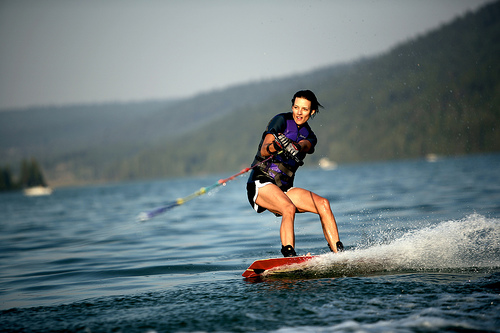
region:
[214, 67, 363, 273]
a woman waterskiing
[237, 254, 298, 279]
a red ski board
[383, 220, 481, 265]
water spraying into the air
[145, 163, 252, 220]
a colorful tether rope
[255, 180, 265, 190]
white trim on shorts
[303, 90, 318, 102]
wet dark brown hair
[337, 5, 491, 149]
a tall hill behind the woman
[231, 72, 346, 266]
a woman wearing a purple lifevest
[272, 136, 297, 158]
gray and black gloves covering hands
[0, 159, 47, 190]
evergreen trees on the shore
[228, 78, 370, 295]
woman water boarding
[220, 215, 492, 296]
water board and wave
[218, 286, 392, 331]
water in sea or ocean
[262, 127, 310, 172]
two hands with a tight grip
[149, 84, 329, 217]
woman holding onto tether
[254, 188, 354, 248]
woman's muscular legs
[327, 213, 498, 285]
white wave of water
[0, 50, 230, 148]
foggy horizon line with trees and hill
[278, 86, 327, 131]
woman's face smiling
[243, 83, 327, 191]
woman wearing life vest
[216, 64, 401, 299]
a surfer in a river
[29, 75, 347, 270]
surfer holds a rope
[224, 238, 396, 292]
a board color red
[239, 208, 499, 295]
splash of water next the board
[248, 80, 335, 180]
woman has black hair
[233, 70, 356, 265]
woman wears black suit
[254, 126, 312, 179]
hands holdings a large handle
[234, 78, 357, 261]
woman is bend backwards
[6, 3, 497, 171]
mountains behind a woman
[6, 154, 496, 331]
water of river is blue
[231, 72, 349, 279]
man surfing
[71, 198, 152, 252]
blue and white ocean waves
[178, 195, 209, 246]
blue and white ocean waves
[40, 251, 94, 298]
blue and white ocean waves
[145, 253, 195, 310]
blue and white ocean waves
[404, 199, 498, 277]
blue and white ocean waves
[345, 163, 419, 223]
blue and white ocean waves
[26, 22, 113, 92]
white clouds in blue sky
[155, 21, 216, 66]
white clouds in blue sky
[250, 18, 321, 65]
white clouds in blue sky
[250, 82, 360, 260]
this is a lady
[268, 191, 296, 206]
the lady is light skinned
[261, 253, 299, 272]
this is a surfboard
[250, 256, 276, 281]
the surfboard is red in color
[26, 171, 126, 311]
this is a water body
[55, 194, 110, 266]
the water is calm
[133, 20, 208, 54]
this is the sky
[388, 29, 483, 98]
this is a hill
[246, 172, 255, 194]
this is a short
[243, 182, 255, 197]
the short is black in color